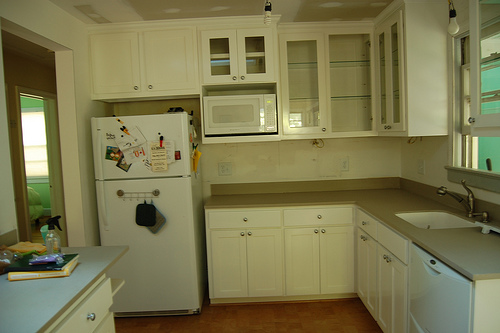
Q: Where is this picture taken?
A: Kitchen.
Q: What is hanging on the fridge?
A: Pot Holders.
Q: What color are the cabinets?
A: White.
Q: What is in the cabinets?
A: Nothing.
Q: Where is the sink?
A: On the right.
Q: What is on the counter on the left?
A: Spray bottle.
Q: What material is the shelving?
A: Glass.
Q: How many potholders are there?
A: 2.